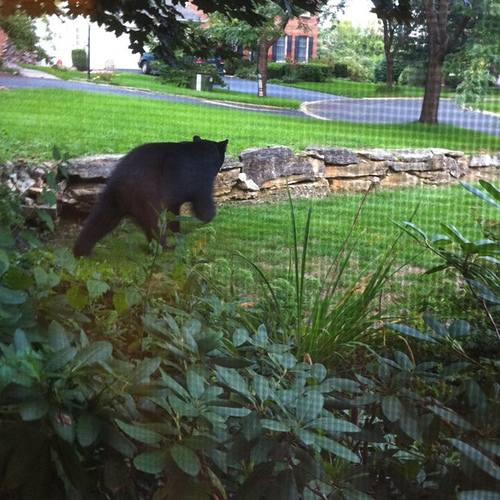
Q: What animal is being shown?
A: Bear.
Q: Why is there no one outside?
A: Safety.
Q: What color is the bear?
A: Black.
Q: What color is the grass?
A: Green.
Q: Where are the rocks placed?
A: Grass.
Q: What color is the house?
A: Red.